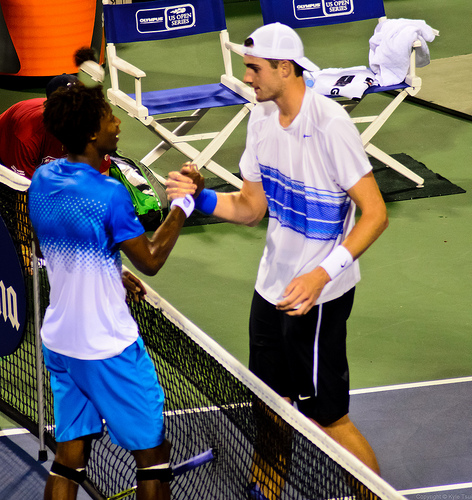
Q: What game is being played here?
A: Tennis.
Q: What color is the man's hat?
A: White.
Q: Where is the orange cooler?
A: In the back left.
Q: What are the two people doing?
A: Shaking hands.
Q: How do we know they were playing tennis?
A: They are on a tennis court and there is a tennis racket.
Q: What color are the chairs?
A: Blue.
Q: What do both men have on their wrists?
A: Sweat bands.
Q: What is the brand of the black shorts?
A: Nike.